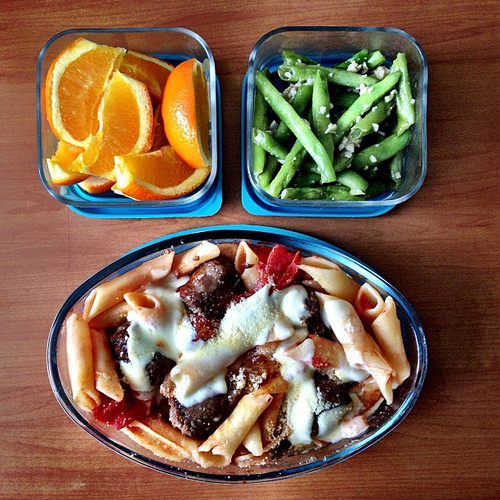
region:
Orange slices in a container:
[34, 23, 219, 215]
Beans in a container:
[244, 24, 426, 214]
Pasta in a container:
[44, 225, 429, 486]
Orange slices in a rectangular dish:
[34, 26, 225, 222]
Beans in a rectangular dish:
[236, 24, 430, 219]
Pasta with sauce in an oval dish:
[44, 219, 431, 484]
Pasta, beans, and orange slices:
[36, 22, 432, 484]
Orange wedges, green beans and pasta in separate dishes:
[34, 28, 433, 484]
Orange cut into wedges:
[34, 24, 222, 220]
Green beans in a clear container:
[241, 26, 428, 223]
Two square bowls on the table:
[31, 22, 431, 217]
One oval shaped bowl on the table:
[43, 223, 433, 484]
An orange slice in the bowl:
[70, 70, 152, 181]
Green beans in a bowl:
[257, 50, 413, 200]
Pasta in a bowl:
[61, 240, 411, 472]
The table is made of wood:
[3, 1, 498, 498]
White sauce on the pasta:
[115, 269, 370, 437]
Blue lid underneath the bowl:
[60, 57, 221, 217]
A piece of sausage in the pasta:
[177, 257, 239, 319]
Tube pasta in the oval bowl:
[62, 317, 97, 414]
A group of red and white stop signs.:
[258, 446, 264, 453]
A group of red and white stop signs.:
[393, 466, 403, 479]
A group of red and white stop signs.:
[23, 397, 35, 424]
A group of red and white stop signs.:
[448, 426, 461, 461]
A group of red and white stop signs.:
[51, 394, 167, 402]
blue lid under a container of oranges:
[36, 51, 225, 217]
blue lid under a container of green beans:
[237, 51, 396, 221]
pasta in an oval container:
[36, 230, 431, 485]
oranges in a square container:
[33, 23, 220, 210]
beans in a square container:
[254, 46, 416, 196]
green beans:
[256, 48, 410, 196]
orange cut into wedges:
[46, 37, 207, 190]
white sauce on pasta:
[121, 270, 364, 443]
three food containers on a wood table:
[32, 21, 462, 493]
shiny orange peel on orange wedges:
[161, 58, 204, 170]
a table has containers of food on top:
[8, 8, 495, 496]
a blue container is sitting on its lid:
[31, 20, 226, 223]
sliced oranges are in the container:
[36, 30, 216, 206]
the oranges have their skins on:
[44, 35, 213, 201]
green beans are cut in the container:
[245, 22, 432, 209]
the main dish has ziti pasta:
[45, 227, 430, 474]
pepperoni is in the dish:
[71, 243, 306, 434]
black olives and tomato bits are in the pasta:
[96, 275, 337, 437]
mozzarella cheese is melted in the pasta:
[121, 283, 358, 444]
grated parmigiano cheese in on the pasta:
[164, 288, 328, 420]